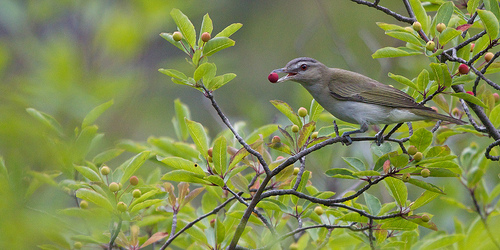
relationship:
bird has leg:
[269, 57, 468, 147] [377, 124, 388, 134]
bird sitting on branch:
[269, 57, 468, 147] [229, 135, 400, 249]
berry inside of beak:
[267, 71, 279, 83] [270, 67, 292, 83]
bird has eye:
[269, 57, 468, 147] [299, 63, 309, 71]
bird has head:
[269, 57, 468, 147] [269, 56, 330, 88]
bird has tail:
[269, 57, 468, 147] [403, 108, 469, 126]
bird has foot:
[269, 57, 468, 147] [337, 132, 353, 146]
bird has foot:
[269, 57, 468, 147] [375, 134, 386, 146]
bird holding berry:
[269, 57, 468, 147] [267, 71, 279, 83]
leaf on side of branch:
[386, 70, 420, 93] [229, 135, 400, 249]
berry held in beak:
[267, 71, 279, 83] [270, 67, 292, 83]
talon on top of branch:
[343, 140, 353, 146] [229, 135, 400, 249]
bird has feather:
[269, 57, 468, 147] [328, 80, 362, 98]